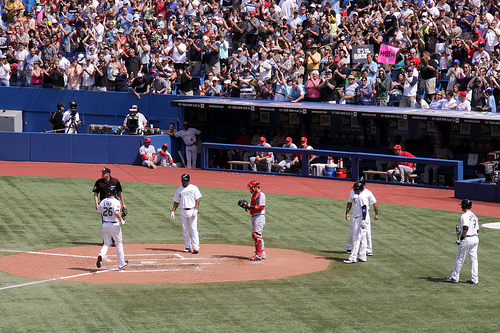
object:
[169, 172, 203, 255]
player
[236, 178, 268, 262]
player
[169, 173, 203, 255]
person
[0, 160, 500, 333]
field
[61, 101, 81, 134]
man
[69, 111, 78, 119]
pictures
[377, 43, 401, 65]
sign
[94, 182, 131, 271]
player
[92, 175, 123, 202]
shirt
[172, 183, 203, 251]
uniform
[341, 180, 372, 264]
player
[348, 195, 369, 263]
uniform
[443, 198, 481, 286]
player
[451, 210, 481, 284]
uniform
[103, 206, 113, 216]
number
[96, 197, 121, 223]
jersey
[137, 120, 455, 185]
team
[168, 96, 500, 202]
dugout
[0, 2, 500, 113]
spectator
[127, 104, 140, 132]
camera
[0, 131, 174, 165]
fence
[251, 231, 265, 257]
pad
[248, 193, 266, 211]
arm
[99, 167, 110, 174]
cap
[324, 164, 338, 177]
cooler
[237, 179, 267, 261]
equipment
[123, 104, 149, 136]
person